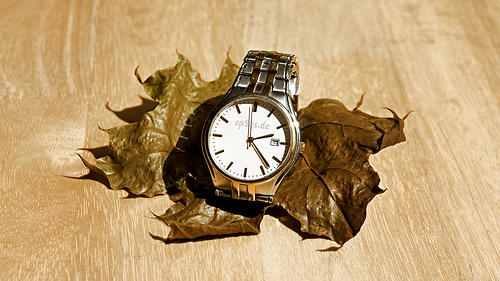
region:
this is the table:
[28, 198, 88, 236]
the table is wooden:
[32, 195, 96, 271]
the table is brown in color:
[12, 193, 96, 255]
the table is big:
[18, 1, 499, 276]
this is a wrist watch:
[201, 37, 302, 209]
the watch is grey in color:
[244, 56, 291, 101]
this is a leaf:
[146, 57, 182, 192]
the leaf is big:
[101, 65, 385, 230]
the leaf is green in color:
[148, 75, 168, 85]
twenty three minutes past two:
[239, 127, 284, 172]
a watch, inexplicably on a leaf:
[45, 37, 420, 267]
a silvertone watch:
[192, 40, 311, 207]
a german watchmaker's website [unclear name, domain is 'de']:
[230, 117, 270, 131]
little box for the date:
[266, 137, 283, 148]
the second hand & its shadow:
[242, 105, 256, 152]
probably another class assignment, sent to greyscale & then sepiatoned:
[0, 1, 498, 279]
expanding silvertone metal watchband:
[226, 45, 306, 115]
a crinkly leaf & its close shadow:
[267, 95, 437, 270]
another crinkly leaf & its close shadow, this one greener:
[63, 40, 248, 198]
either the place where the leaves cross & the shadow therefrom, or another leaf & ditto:
[137, 182, 271, 261]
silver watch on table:
[195, 36, 315, 217]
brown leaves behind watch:
[75, 60, 380, 235]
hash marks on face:
[220, 100, 285, 175]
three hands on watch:
[240, 122, 271, 172]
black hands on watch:
[245, 117, 270, 172]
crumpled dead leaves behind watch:
[135, 61, 385, 248]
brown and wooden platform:
[25, 20, 96, 100]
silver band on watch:
[212, 50, 292, 90]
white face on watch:
[216, 105, 278, 166]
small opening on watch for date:
[269, 136, 283, 149]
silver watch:
[191, 41, 307, 205]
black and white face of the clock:
[207, 98, 297, 182]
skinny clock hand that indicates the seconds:
[242, 106, 257, 143]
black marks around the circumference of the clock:
[208, 93, 287, 185]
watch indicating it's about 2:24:
[208, 93, 301, 192]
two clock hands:
[244, 132, 279, 165]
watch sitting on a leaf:
[94, 25, 408, 266]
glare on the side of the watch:
[289, 115, 301, 132]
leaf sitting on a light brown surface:
[1, 3, 494, 278]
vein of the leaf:
[311, 155, 369, 230]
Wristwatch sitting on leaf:
[223, 46, 312, 212]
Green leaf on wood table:
[108, 63, 442, 223]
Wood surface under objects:
[8, 10, 498, 265]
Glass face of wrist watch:
[218, 91, 280, 168]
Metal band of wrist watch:
[225, 30, 307, 95]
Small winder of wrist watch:
[299, 141, 306, 148]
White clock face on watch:
[205, 89, 304, 170]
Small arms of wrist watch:
[238, 102, 268, 167]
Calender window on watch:
[263, 135, 281, 149]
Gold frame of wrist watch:
[207, 103, 301, 203]